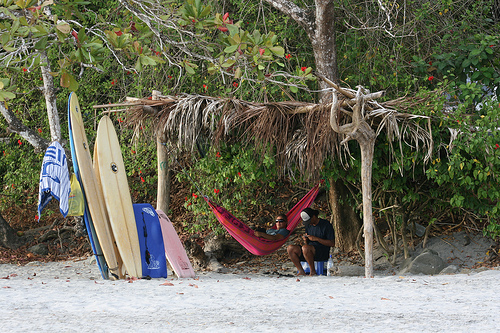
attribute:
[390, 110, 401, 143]
leaf — dry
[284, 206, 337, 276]
person — sitting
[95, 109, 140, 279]
surfboard — lined up, standing up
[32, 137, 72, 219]
towel — hanging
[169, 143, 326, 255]
hammock — red, hanging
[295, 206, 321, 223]
hat — black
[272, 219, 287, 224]
sunglasses — these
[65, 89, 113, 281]
boogie board — blue, lined up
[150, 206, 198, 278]
boogie board — lined up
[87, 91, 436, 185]
roof — grass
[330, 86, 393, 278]
pole — wood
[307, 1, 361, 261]
tree stem — thick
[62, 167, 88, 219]
bag — yellow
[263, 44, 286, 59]
leaf — green